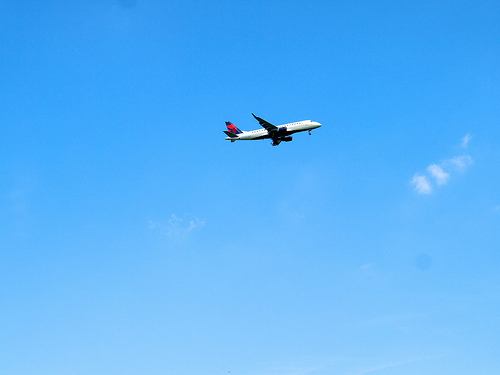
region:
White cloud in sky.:
[419, 155, 458, 205]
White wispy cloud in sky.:
[172, 206, 209, 229]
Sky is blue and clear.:
[33, 233, 103, 313]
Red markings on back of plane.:
[226, 120, 237, 140]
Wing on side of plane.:
[249, 110, 281, 142]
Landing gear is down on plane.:
[303, 128, 317, 140]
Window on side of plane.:
[286, 117, 311, 131]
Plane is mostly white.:
[237, 108, 326, 153]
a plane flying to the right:
[216, 104, 328, 154]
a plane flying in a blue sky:
[161, 27, 385, 230]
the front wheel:
[305, 127, 314, 137]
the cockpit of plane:
[306, 117, 318, 128]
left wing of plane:
[248, 110, 279, 133]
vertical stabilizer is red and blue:
[220, 116, 244, 131]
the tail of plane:
[219, 117, 244, 144]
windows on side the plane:
[250, 119, 299, 133]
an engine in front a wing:
[276, 124, 291, 134]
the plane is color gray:
[211, 105, 326, 149]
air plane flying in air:
[183, 84, 330, 212]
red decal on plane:
[218, 117, 242, 139]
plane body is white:
[223, 105, 329, 161]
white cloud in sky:
[408, 131, 486, 218]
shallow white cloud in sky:
[130, 199, 225, 267]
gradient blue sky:
[47, 30, 219, 373]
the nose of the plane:
[308, 116, 323, 131]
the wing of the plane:
[245, 107, 276, 137]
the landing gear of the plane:
[265, 133, 296, 148]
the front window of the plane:
[285, 114, 330, 130]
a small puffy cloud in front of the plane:
[411, 130, 476, 191]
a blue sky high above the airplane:
[2, 1, 493, 369]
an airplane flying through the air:
[225, 114, 324, 144]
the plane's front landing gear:
[307, 128, 311, 133]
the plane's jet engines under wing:
[275, 124, 291, 142]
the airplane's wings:
[252, 112, 281, 146]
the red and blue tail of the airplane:
[224, 119, 241, 142]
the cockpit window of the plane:
[308, 118, 314, 123]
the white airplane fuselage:
[236, 117, 321, 140]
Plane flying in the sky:
[4, 4, 498, 372]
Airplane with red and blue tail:
[216, 109, 326, 149]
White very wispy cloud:
[388, 129, 488, 199]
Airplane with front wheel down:
[219, 109, 330, 147]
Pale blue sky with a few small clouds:
[1, 6, 494, 371]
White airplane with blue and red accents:
[219, 109, 327, 149]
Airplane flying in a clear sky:
[4, 7, 498, 370]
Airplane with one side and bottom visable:
[216, 112, 322, 148]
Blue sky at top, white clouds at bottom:
[4, 7, 496, 369]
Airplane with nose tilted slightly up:
[214, 108, 323, 150]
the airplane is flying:
[223, 111, 320, 146]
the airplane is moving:
[221, 113, 321, 144]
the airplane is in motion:
[222, 113, 322, 145]